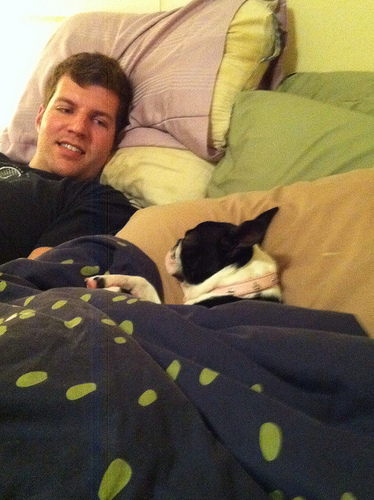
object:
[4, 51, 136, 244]
man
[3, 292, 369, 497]
bed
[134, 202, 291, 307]
dog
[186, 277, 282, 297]
collar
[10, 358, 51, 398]
designs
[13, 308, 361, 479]
blanket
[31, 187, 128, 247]
sleeves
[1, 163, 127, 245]
shirt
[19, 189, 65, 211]
black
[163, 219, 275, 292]
head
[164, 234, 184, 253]
nose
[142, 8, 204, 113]
purple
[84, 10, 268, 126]
case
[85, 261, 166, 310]
paw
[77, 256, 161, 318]
top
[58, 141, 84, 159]
teeth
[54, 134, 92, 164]
mouth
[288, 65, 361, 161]
two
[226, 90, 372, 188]
pillows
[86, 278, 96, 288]
pad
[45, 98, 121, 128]
looking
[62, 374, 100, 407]
dots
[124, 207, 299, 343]
resting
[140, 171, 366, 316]
pillow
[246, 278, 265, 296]
studs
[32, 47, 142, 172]
head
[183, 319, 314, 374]
folds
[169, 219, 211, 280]
face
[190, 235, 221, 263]
black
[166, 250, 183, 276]
white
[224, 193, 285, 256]
ears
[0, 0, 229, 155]
pillow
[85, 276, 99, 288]
pink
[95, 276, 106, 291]
black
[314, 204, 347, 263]
tan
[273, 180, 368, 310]
case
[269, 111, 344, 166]
green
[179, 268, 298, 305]
neck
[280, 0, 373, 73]
wall